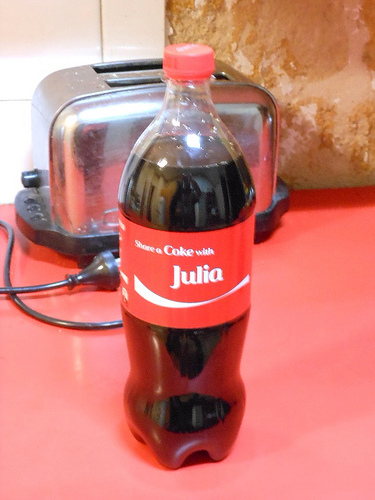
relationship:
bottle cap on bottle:
[162, 42, 215, 78] [116, 44, 255, 467]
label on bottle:
[114, 218, 255, 331] [108, 36, 262, 473]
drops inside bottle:
[128, 87, 243, 168] [116, 44, 255, 467]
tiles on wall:
[2, 0, 170, 203] [1, 1, 373, 206]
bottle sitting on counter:
[116, 44, 255, 467] [2, 184, 374, 498]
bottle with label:
[116, 44, 255, 467] [114, 218, 255, 331]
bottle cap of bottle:
[162, 42, 215, 78] [116, 44, 255, 467]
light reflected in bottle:
[180, 129, 206, 152] [116, 44, 255, 467]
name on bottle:
[167, 262, 222, 288] [116, 44, 255, 467]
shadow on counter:
[288, 188, 373, 209] [5, 463, 373, 497]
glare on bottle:
[184, 133, 203, 149] [116, 44, 255, 467]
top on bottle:
[162, 35, 217, 84] [64, 24, 297, 468]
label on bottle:
[118, 212, 255, 331] [116, 44, 255, 467]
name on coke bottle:
[169, 264, 223, 289] [107, 20, 292, 433]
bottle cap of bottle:
[162, 42, 215, 78] [64, 24, 297, 468]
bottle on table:
[116, 44, 255, 469] [267, 173, 373, 305]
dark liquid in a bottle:
[116, 153, 257, 229] [116, 44, 255, 467]